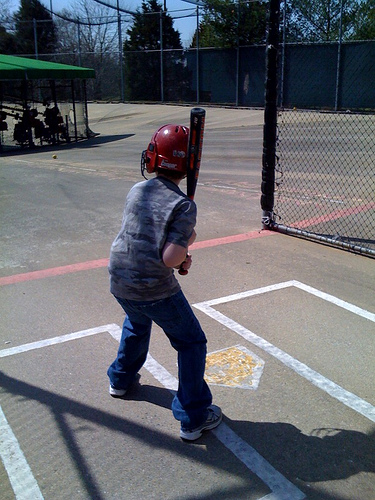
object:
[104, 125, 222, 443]
boy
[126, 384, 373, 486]
shadow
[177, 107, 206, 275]
bat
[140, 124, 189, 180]
helmet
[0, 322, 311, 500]
lines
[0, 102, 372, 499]
ground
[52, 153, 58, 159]
ball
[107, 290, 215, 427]
jeans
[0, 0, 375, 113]
fence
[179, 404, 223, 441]
shoe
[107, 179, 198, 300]
shirt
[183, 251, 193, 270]
hand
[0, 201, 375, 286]
line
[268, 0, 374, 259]
net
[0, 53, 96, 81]
roof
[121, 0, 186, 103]
tree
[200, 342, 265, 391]
home base plate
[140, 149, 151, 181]
mask